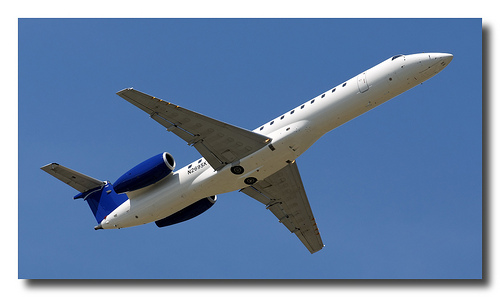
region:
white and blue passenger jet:
[51, 34, 468, 263]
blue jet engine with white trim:
[108, 140, 183, 202]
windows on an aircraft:
[240, 70, 358, 134]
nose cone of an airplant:
[402, 40, 464, 92]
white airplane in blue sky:
[46, 27, 466, 254]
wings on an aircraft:
[116, 73, 338, 255]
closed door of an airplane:
[352, 58, 377, 100]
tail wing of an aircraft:
[33, 140, 124, 247]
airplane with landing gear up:
[44, 36, 459, 266]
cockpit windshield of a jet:
[386, 43, 406, 67]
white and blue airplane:
[37, 35, 445, 262]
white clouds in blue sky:
[361, 171, 402, 215]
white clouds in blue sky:
[395, 161, 447, 202]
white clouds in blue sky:
[341, 182, 402, 247]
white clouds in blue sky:
[218, 232, 256, 264]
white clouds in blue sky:
[28, 32, 76, 74]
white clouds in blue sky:
[225, 36, 276, 104]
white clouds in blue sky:
[90, 38, 180, 66]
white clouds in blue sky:
[48, 82, 100, 126]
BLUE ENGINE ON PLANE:
[111, 150, 178, 195]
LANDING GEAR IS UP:
[219, 164, 262, 189]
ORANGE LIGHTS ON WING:
[147, 91, 185, 113]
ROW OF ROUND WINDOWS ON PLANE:
[254, 79, 354, 134]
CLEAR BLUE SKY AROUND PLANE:
[353, 143, 462, 245]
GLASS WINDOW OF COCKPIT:
[390, 50, 408, 62]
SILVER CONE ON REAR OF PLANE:
[90, 221, 105, 232]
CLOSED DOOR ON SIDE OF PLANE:
[352, 67, 374, 97]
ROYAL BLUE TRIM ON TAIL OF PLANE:
[73, 176, 127, 221]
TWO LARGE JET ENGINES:
[111, 151, 218, 231]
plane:
[18, 46, 468, 253]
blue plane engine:
[107, 138, 191, 183]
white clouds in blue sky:
[354, 238, 411, 258]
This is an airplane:
[30, 43, 474, 273]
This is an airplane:
[35, 35, 496, 293]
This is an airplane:
[32, 30, 467, 272]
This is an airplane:
[37, 42, 468, 280]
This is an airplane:
[26, 47, 453, 285]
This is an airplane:
[34, 42, 461, 286]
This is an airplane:
[27, 47, 457, 274]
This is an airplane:
[31, 49, 481, 265]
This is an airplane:
[37, 41, 453, 268]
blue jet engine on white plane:
[109, 140, 186, 196]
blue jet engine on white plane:
[104, 140, 186, 197]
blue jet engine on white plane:
[106, 140, 191, 196]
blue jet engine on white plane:
[103, 140, 200, 202]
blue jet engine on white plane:
[101, 134, 194, 199]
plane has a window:
[269, 119, 274, 124]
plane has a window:
[280, 112, 285, 119]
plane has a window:
[261, 123, 266, 129]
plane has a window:
[299, 102, 305, 106]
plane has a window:
[309, 97, 314, 102]